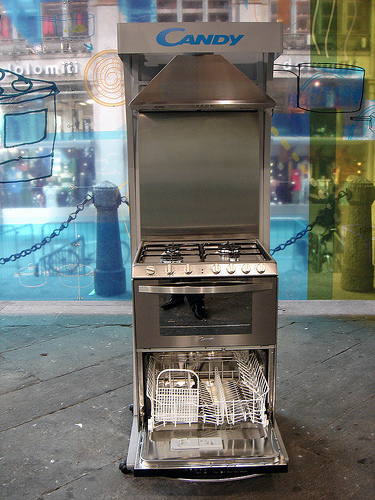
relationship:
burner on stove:
[141, 243, 201, 258] [137, 236, 279, 285]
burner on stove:
[199, 252, 275, 262] [137, 236, 279, 285]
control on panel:
[145, 265, 156, 275] [133, 265, 278, 276]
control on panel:
[162, 267, 176, 276] [133, 265, 278, 276]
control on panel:
[184, 264, 192, 274] [133, 265, 278, 276]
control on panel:
[211, 266, 223, 276] [133, 265, 278, 276]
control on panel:
[224, 265, 238, 275] [133, 265, 278, 276]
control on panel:
[240, 267, 252, 278] [133, 265, 278, 276]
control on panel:
[254, 266, 267, 276] [133, 265, 278, 276]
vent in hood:
[151, 94, 257, 114] [131, 49, 274, 237]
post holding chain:
[86, 179, 127, 299] [2, 188, 350, 260]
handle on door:
[139, 287, 279, 297] [131, 280, 277, 348]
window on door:
[156, 284, 251, 335] [131, 280, 277, 348]